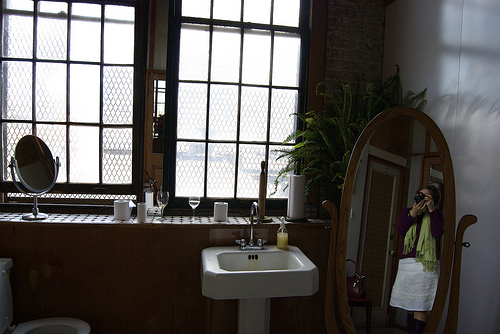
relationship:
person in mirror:
[386, 182, 453, 304] [321, 100, 479, 324]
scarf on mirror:
[401, 215, 441, 272] [328, 96, 470, 307]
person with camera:
[386, 184, 441, 333] [411, 185, 430, 209]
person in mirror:
[386, 184, 441, 333] [321, 100, 479, 324]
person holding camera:
[386, 184, 441, 333] [415, 190, 425, 202]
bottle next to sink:
[276, 223, 288, 248] [190, 197, 328, 327]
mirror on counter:
[11, 125, 61, 216] [3, 203, 202, 323]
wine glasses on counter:
[155, 184, 203, 228] [3, 203, 202, 323]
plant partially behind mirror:
[269, 64, 428, 219] [321, 100, 479, 324]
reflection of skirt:
[387, 174, 442, 316] [387, 261, 439, 311]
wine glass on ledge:
[156, 188, 170, 221] [0, 209, 326, 226]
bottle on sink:
[278, 229, 292, 248] [194, 211, 354, 319]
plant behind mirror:
[277, 67, 428, 229] [331, 95, 473, 332]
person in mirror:
[386, 184, 441, 333] [340, 119, 460, 307]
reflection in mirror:
[347, 115, 444, 333] [340, 119, 460, 307]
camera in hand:
[410, 186, 428, 205] [412, 198, 429, 211]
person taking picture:
[386, 184, 441, 333] [411, 193, 425, 203]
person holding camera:
[386, 184, 441, 333] [413, 192, 429, 202]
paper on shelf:
[114, 199, 130, 221] [0, 210, 319, 235]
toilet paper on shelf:
[213, 201, 226, 220] [0, 210, 319, 235]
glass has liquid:
[189, 192, 202, 220] [184, 196, 201, 216]